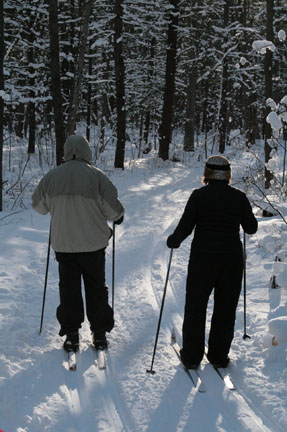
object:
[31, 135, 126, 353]
man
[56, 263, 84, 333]
leg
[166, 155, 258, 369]
lady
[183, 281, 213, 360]
leg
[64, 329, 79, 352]
feet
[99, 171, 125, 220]
arm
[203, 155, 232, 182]
hat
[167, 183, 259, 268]
jacket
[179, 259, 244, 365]
pants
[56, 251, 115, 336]
pants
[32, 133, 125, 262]
jacket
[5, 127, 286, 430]
snow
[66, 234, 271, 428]
tracks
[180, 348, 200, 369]
boots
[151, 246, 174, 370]
poles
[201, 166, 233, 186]
hair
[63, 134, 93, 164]
hood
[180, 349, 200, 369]
feet